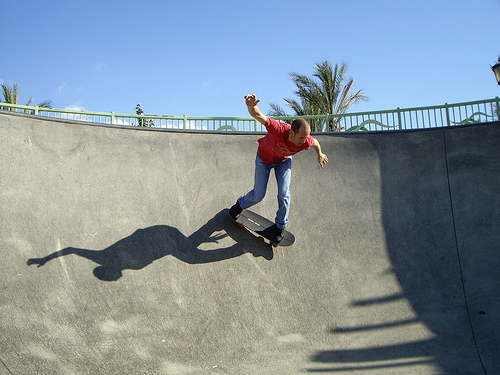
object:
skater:
[230, 94, 329, 243]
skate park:
[0, 0, 499, 375]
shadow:
[26, 217, 248, 281]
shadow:
[222, 209, 273, 261]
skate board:
[229, 206, 296, 247]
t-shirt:
[257, 118, 314, 164]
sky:
[0, 1, 499, 63]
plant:
[291, 60, 367, 130]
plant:
[2, 83, 17, 111]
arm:
[249, 107, 268, 125]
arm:
[311, 138, 322, 154]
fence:
[0, 100, 499, 134]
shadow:
[302, 135, 496, 375]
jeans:
[238, 155, 291, 228]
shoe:
[229, 200, 242, 220]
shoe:
[274, 228, 285, 243]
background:
[0, 0, 499, 248]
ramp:
[0, 134, 499, 375]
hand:
[244, 94, 260, 106]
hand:
[318, 153, 329, 167]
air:
[199, 46, 299, 70]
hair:
[291, 120, 302, 137]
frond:
[311, 61, 344, 127]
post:
[111, 112, 114, 123]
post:
[397, 107, 402, 129]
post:
[445, 103, 450, 126]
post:
[183, 115, 187, 128]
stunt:
[228, 94, 328, 248]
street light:
[492, 61, 500, 85]